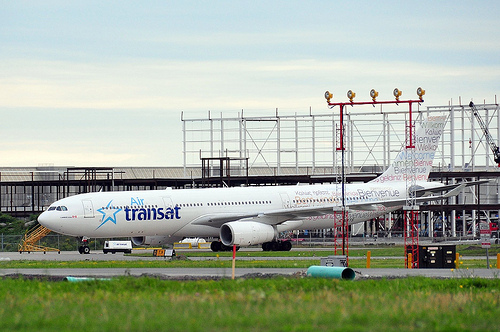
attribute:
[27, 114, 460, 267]
plane — white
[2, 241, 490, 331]
grass — green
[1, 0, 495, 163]
sky — blue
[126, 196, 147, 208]
word — Air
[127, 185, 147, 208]
word — Air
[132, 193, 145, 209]
word — Air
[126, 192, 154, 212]
word — Air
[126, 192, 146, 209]
word — Air